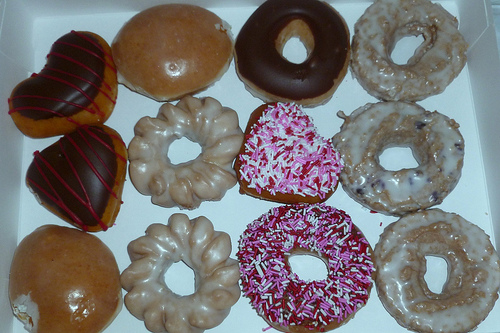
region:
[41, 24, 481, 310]
many donuts in box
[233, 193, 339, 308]
red and white sprinkles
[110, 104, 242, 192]
brown iced crullers in box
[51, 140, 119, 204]
heart shaped donuts in box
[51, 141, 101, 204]
red and brown icing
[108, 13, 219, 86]
jelly filled glazed donuts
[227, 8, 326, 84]
ring donut with brown icing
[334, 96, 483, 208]
ring donuts with raisins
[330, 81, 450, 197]
iced donut with raisins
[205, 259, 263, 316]
Heart shaped donut with sprinkles.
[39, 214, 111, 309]
Heart shaped donut with sprinkles.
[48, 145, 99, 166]
Heart shaped donut with sprinkles.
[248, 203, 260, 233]
part of a table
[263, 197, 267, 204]
edge of a box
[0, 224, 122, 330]
glazed filled doughnute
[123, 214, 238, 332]
white glazed spiral doughnut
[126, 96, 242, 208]
white glazed spiral doughnut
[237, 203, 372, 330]
doughnut with white and pink sprinkles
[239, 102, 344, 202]
heart-shaped doughnut with white and pink sprinkles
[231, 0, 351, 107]
chocolate covered doughnut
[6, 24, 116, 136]
heart-shaped doughnut with chocolate glaze and red drizzle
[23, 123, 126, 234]
heart-shaped doughnut with chocolate glaze and red drizzle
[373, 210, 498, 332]
white glazed doughnut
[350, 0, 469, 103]
white glazed doughnut